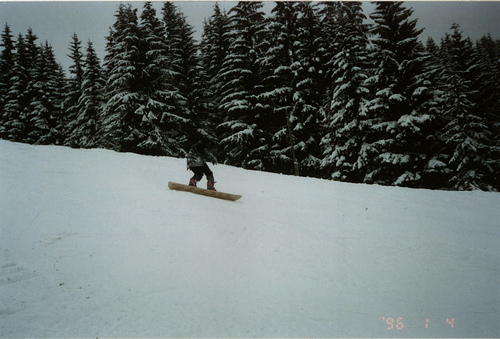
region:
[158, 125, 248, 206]
Skier going down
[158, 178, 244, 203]
Skyboard is yellow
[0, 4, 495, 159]
Pines on side of snow trail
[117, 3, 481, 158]
Pines are covered with snow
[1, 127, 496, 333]
Hill covered with snow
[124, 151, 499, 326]
Hill has a slope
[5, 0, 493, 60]
Sky is cloudy and grey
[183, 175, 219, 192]
Boots are yellow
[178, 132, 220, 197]
Skier wears black pants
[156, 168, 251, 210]
Snowboard is long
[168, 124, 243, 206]
a snow boarder is sliding down a hil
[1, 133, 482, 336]
the hill is full of snow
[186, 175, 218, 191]
the snow boarder is wearing boots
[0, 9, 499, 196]
a group of pine trees are in the background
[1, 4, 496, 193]
the pine trees are covered with snow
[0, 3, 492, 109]
the sky is grey in color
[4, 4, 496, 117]
the sky is overcast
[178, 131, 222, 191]
the snow boarder is covered with snow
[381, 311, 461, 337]
numbers are printed on the photograph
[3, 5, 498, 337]
the photo was taken outside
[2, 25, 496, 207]
snow covered trees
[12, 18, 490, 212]
a background of fir trees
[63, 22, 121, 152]
a tall evergreen tree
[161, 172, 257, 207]
a light colored snowboard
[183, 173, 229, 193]
red and black snowboard boots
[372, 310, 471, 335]
the date written in red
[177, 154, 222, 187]
pair of black snowboard pants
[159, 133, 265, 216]
a person snowboarding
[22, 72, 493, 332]
a winter scene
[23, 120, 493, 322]
well groomed ski slope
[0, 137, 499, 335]
snowy sloped hillside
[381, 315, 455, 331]
date recorded in red lettering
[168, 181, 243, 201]
long yellow and red snowboard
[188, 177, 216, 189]
two black and red boots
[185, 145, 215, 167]
black coat dusted with snow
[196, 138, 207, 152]
skier wearing a black ski mask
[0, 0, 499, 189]
pine trees covered in snow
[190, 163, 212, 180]
black snow pants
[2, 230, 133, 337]
ski marks in snow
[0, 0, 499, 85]
cloudy sky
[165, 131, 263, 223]
Person is snowboarding in snow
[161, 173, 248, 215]
Persons snowboard is brown in color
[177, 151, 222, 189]
Person is wearing black pants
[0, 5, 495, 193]
Pine trees are in the background of image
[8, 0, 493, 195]
Pine trees have snow covering them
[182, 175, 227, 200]
Person's snow boots are red and black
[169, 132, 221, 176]
Person is wearing a heavy gray coat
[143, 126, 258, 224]
Person is distant from the camera shot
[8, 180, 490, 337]
Snow is pearl white in color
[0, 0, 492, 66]
Sky is gray and cloudy